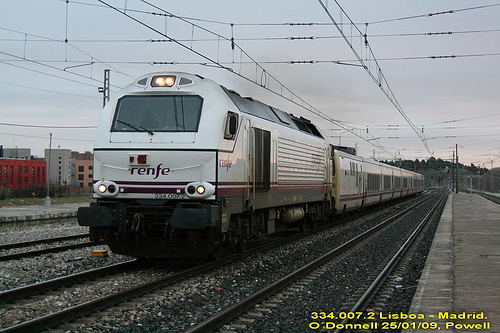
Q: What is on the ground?
A: Railroad tracks.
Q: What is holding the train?
A: Train Tracks.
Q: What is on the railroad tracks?
A: The train.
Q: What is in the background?
A: Buildings.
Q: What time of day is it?
A: Dusk.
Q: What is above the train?
A: Electrical wiring.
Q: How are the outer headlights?
A: On.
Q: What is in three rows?
A: Tracks.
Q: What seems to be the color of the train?
A: Silver.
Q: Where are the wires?
A: Above the train.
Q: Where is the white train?
A: On a track.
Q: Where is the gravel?
A: Between the train tracks.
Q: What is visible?
A: Railroad.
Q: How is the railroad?
A: Visible.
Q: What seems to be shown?
A: Railroad.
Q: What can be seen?
A: Railroad.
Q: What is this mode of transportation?
A: Train.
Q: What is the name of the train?
A: Renfe.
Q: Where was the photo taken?
A: Spain.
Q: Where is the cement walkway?
A: On the right side along tracks.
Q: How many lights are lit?
A: Four.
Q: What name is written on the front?
A: Renfe.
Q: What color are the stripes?
A: Red.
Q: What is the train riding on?
A: Tracks.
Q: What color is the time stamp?
A: Yellow.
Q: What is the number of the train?
A: 3340072.